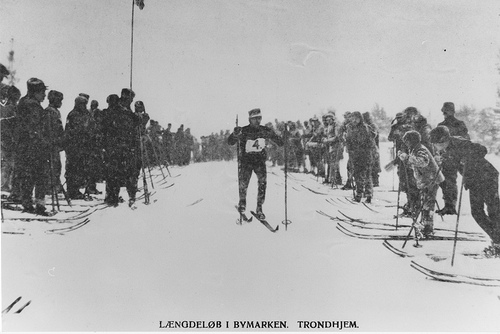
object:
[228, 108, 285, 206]
man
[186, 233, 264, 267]
snow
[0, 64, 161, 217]
group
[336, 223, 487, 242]
skis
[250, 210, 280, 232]
ski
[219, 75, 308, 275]
skier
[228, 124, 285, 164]
jacket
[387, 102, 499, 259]
people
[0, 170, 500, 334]
ground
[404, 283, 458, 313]
snow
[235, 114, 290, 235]
poles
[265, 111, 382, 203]
people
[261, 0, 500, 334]
side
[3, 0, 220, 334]
side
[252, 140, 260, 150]
4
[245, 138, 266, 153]
sign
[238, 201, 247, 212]
feet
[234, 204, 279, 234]
skis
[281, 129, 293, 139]
hand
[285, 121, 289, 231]
pole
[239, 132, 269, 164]
bib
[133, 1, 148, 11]
flag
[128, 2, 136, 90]
flagpole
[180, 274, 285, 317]
snow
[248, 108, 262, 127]
head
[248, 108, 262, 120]
hat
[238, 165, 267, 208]
legs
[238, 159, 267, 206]
pants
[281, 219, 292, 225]
ring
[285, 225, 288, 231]
pole tip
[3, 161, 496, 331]
slope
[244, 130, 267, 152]
skier's chest